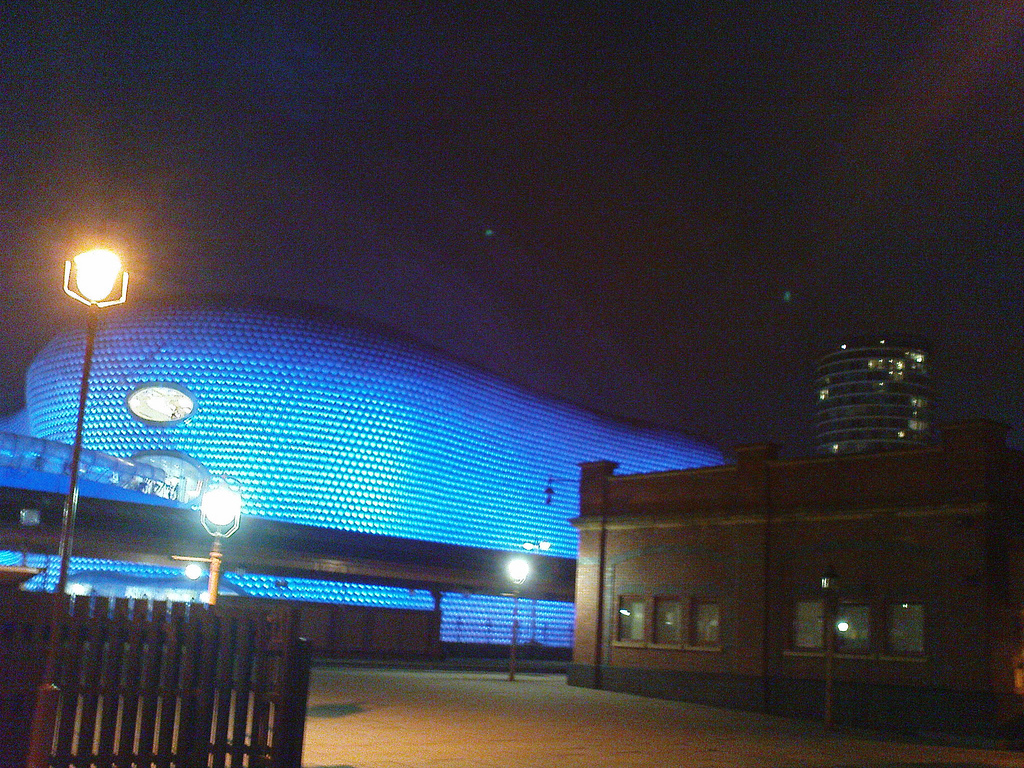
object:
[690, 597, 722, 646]
window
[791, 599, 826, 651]
window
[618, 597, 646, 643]
window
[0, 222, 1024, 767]
city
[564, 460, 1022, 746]
building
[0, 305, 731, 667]
building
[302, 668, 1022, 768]
sidewalk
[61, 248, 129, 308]
light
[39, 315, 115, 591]
pole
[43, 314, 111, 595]
pole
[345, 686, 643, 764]
pavement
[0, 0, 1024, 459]
sky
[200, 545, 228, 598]
post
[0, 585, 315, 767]
fence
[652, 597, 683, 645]
window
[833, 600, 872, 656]
window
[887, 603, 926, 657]
window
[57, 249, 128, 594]
light post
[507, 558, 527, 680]
lamp post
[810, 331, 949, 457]
building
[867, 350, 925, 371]
lights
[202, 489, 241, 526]
light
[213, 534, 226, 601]
post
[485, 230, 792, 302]
stars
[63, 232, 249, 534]
lights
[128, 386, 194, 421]
light